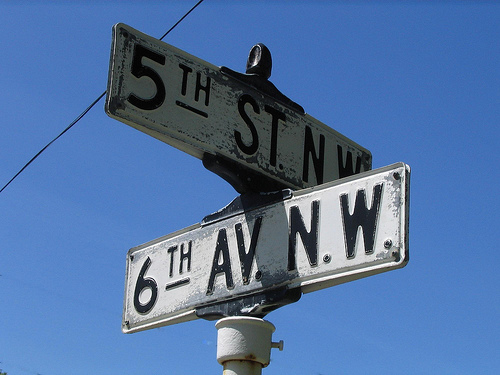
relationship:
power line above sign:
[1, 1, 205, 194] [104, 21, 411, 334]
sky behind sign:
[1, 1, 499, 375] [104, 21, 411, 334]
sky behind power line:
[1, 1, 499, 375] [1, 1, 205, 194]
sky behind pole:
[1, 1, 499, 375] [214, 316, 276, 375]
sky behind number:
[1, 1, 499, 375] [128, 42, 166, 111]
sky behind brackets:
[1, 1, 499, 375] [200, 151, 294, 226]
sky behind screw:
[1, 1, 499, 375] [272, 340, 284, 352]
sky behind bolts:
[1, 1, 499, 375] [383, 173, 403, 251]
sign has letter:
[121, 161, 411, 335] [133, 182, 384, 314]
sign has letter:
[104, 21, 411, 334] [128, 43, 362, 179]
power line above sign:
[0, 0, 204, 190] [104, 21, 411, 334]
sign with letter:
[104, 21, 411, 334] [133, 182, 384, 314]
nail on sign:
[278, 162, 284, 169] [104, 21, 411, 334]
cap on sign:
[245, 41, 273, 78] [104, 21, 411, 334]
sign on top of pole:
[104, 21, 411, 334] [214, 316, 276, 375]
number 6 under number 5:
[132, 257, 160, 315] [127, 41, 166, 111]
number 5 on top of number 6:
[127, 41, 166, 111] [132, 257, 160, 315]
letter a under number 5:
[205, 228, 234, 294] [127, 41, 166, 111]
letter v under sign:
[233, 217, 262, 284] [104, 21, 411, 334]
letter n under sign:
[287, 199, 318, 271] [104, 21, 411, 334]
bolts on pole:
[383, 173, 403, 251] [214, 315, 282, 371]